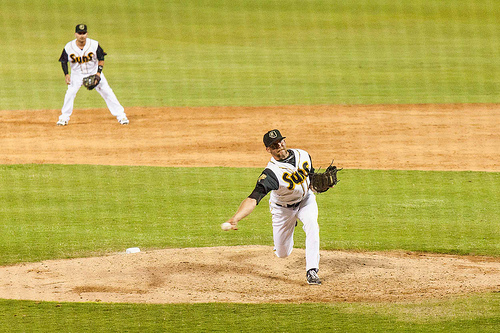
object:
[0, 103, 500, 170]
dirt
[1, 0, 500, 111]
green grass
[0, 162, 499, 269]
green grass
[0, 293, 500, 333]
green grass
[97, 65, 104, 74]
band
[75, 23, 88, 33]
cap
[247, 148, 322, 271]
uniform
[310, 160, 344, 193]
glove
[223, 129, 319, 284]
athlete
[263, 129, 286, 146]
hat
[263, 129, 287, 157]
head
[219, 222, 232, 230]
baseball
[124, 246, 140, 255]
box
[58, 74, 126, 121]
pants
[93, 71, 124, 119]
legs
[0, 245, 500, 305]
mound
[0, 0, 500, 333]
baseball field